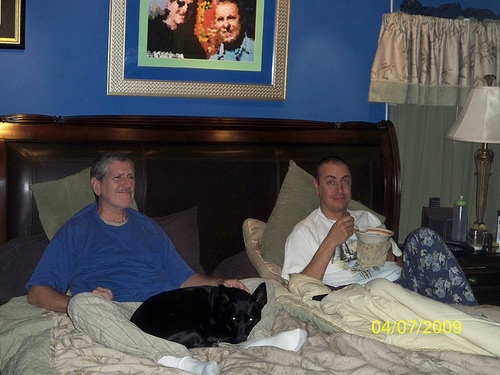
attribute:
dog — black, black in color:
[130, 273, 271, 349]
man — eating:
[282, 158, 484, 309]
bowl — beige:
[344, 218, 397, 243]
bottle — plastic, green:
[454, 191, 471, 245]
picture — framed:
[103, 1, 287, 99]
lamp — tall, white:
[448, 73, 500, 252]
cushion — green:
[261, 160, 389, 273]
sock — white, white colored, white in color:
[156, 354, 219, 374]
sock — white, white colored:
[252, 323, 308, 355]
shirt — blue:
[27, 202, 206, 310]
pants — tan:
[63, 296, 253, 361]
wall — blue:
[4, 5, 393, 120]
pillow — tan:
[242, 215, 290, 286]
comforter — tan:
[11, 276, 500, 374]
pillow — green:
[34, 167, 141, 242]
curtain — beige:
[370, 12, 500, 108]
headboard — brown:
[4, 111, 405, 295]